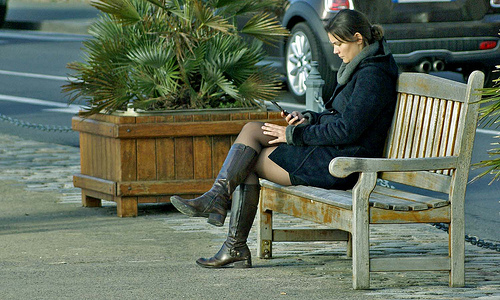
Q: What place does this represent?
A: It represents the road.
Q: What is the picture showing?
A: It is showing a road.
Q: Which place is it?
A: It is a road.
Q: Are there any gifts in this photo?
A: No, there are no gifts.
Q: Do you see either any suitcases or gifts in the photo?
A: No, there are no gifts or suitcases.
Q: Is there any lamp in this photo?
A: No, there are no lamps.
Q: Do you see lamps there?
A: No, there are no lamps.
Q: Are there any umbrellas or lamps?
A: No, there are no lamps or umbrellas.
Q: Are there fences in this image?
A: No, there are no fences.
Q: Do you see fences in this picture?
A: No, there are no fences.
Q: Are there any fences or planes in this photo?
A: No, there are no fences or planes.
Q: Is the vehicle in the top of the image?
A: Yes, the vehicle is in the top of the image.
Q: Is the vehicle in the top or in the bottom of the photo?
A: The vehicle is in the top of the image.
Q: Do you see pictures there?
A: No, there are no pictures.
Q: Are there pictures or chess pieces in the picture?
A: No, there are no pictures or chess pieces.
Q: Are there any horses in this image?
A: No, there are no horses.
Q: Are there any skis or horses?
A: No, there are no horses or skis.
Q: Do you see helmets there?
A: No, there are no helmets.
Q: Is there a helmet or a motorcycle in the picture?
A: No, there are no helmets or motorcycles.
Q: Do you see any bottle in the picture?
A: No, there are no bottles.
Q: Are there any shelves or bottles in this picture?
A: No, there are no bottles or shelves.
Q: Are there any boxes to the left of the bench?
A: Yes, there is a box to the left of the bench.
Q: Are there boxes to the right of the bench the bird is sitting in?
A: No, the box is to the left of the bench.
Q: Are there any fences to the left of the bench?
A: No, there is a box to the left of the bench.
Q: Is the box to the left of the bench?
A: Yes, the box is to the left of the bench.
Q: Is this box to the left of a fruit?
A: No, the box is to the left of the bench.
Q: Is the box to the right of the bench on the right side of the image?
A: No, the box is to the left of the bench.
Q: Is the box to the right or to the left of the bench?
A: The box is to the left of the bench.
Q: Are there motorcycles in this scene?
A: No, there are no motorcycles.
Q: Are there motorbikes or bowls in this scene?
A: No, there are no motorbikes or bowls.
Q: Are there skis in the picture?
A: No, there are no skis.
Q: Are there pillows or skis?
A: No, there are no skis or pillows.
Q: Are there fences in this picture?
A: No, there are no fences.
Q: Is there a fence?
A: No, there are no fences.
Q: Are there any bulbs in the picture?
A: No, there are no bulbs.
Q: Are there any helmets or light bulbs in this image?
A: No, there are no light bulbs or helmets.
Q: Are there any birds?
A: Yes, there is a bird.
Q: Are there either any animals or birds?
A: Yes, there is a bird.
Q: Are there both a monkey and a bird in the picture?
A: No, there is a bird but no monkeys.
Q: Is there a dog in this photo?
A: No, there are no dogs.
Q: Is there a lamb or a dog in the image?
A: No, there are no dogs or lambs.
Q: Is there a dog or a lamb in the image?
A: No, there are no dogs or lambs.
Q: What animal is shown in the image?
A: The animal is a bird.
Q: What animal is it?
A: The animal is a bird.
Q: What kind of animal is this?
A: This is a bird.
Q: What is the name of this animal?
A: This is a bird.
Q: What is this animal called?
A: This is a bird.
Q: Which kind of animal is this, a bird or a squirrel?
A: This is a bird.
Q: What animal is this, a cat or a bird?
A: This is a bird.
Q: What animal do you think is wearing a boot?
A: The bird is wearing a boot.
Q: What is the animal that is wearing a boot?
A: The animal is a bird.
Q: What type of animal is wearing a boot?
A: The animal is a bird.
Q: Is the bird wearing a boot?
A: Yes, the bird is wearing a boot.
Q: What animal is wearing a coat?
A: The bird is wearing a coat.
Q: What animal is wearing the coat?
A: The bird is wearing a coat.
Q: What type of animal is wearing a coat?
A: The animal is a bird.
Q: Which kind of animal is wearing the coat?
A: The animal is a bird.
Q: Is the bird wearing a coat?
A: Yes, the bird is wearing a coat.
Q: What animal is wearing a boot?
A: The bird is wearing a boot.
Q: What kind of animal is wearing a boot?
A: The animal is a bird.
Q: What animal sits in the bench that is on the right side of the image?
A: The bird sits in the bench.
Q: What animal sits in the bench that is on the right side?
A: The animal is a bird.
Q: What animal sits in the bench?
A: The animal is a bird.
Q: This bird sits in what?
A: The bird sits in the bench.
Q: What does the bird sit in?
A: The bird sits in the bench.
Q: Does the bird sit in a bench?
A: Yes, the bird sits in a bench.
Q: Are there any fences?
A: No, there are no fences.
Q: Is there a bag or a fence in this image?
A: No, there are no fences or bags.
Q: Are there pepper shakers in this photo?
A: No, there are no pepper shakers.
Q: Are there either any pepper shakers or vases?
A: No, there are no pepper shakers or vases.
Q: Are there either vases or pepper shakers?
A: No, there are no pepper shakers or vases.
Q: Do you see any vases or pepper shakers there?
A: No, there are no pepper shakers or vases.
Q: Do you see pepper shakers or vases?
A: No, there are no pepper shakers or vases.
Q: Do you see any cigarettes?
A: No, there are no cigarettes.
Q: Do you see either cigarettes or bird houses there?
A: No, there are no cigarettes or bird houses.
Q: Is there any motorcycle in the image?
A: No, there are no motorcycles.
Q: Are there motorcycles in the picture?
A: No, there are no motorcycles.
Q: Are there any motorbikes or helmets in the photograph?
A: No, there are no motorbikes or helmets.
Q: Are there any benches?
A: Yes, there is a bench.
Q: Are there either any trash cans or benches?
A: Yes, there is a bench.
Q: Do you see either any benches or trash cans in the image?
A: Yes, there is a bench.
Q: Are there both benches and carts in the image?
A: No, there is a bench but no carts.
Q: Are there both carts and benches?
A: No, there is a bench but no carts.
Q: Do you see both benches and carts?
A: No, there is a bench but no carts.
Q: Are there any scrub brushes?
A: No, there are no scrub brushes.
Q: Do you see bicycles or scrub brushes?
A: No, there are no scrub brushes or bicycles.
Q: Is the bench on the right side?
A: Yes, the bench is on the right of the image.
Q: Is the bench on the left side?
A: No, the bench is on the right of the image.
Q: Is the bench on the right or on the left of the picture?
A: The bench is on the right of the image.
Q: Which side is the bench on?
A: The bench is on the right of the image.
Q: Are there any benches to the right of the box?
A: Yes, there is a bench to the right of the box.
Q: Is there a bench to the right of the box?
A: Yes, there is a bench to the right of the box.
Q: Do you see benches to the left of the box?
A: No, the bench is to the right of the box.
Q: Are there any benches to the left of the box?
A: No, the bench is to the right of the box.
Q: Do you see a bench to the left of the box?
A: No, the bench is to the right of the box.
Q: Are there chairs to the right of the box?
A: No, there is a bench to the right of the box.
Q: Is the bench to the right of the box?
A: Yes, the bench is to the right of the box.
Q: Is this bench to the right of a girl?
A: No, the bench is to the right of the box.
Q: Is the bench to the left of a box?
A: No, the bench is to the right of a box.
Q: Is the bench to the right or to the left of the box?
A: The bench is to the right of the box.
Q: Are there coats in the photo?
A: Yes, there is a coat.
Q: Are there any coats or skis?
A: Yes, there is a coat.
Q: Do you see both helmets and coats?
A: No, there is a coat but no helmets.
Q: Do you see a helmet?
A: No, there are no helmets.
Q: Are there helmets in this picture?
A: No, there are no helmets.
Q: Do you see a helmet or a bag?
A: No, there are no helmets or bags.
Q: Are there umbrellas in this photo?
A: No, there are no umbrellas.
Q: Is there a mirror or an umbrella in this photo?
A: No, there are no umbrellas or mirrors.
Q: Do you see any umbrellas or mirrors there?
A: No, there are no umbrellas or mirrors.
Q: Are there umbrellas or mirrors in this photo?
A: No, there are no umbrellas or mirrors.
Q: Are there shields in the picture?
A: No, there are no shields.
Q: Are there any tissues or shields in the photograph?
A: No, there are no shields or tissues.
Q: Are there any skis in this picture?
A: No, there are no skis.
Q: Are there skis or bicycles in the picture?
A: No, there are no skis or bicycles.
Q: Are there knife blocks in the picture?
A: No, there are no knife blocks.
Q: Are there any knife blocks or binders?
A: No, there are no knife blocks or binders.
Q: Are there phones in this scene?
A: Yes, there is a phone.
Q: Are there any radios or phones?
A: Yes, there is a phone.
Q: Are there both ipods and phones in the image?
A: No, there is a phone but no ipods.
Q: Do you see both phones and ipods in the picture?
A: No, there is a phone but no ipods.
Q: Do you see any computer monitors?
A: No, there are no computer monitors.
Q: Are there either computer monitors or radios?
A: No, there are no computer monitors or radios.